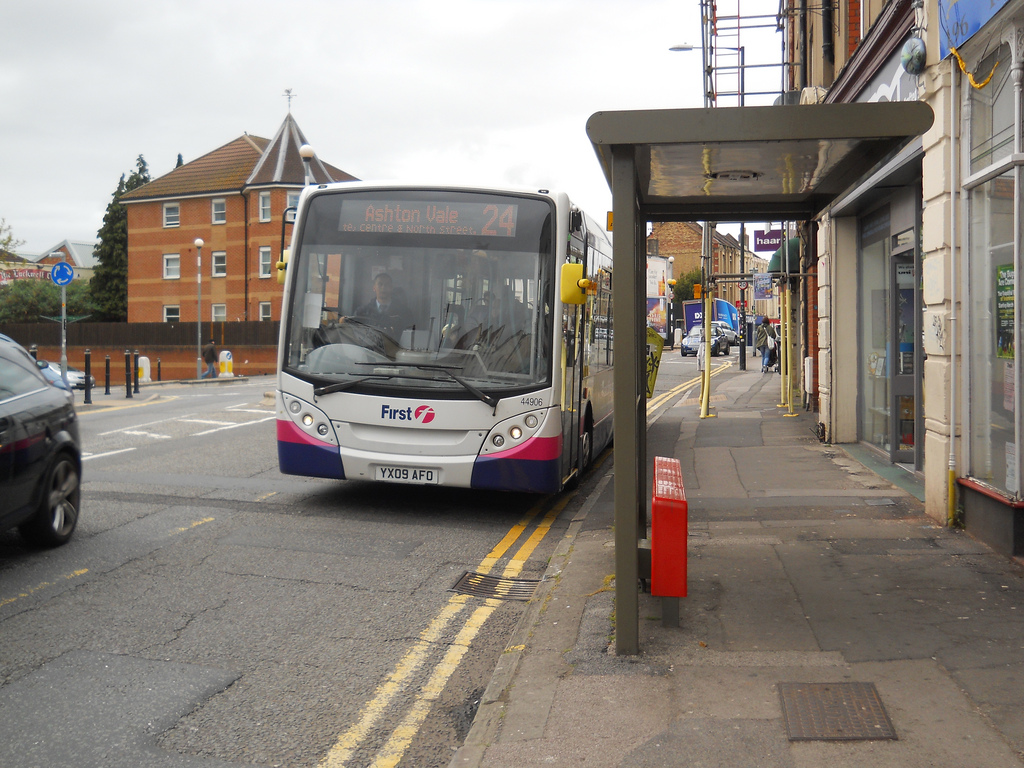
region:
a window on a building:
[152, 198, 173, 224]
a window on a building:
[159, 301, 172, 311]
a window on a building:
[251, 296, 264, 304]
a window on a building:
[163, 238, 170, 268]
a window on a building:
[251, 248, 267, 271]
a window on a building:
[277, 186, 300, 235]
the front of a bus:
[273, 188, 574, 536]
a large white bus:
[229, 148, 670, 488]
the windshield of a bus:
[329, 243, 513, 389]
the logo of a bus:
[337, 401, 456, 431]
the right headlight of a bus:
[254, 393, 337, 451]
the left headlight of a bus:
[457, 412, 556, 464]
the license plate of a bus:
[356, 450, 451, 499]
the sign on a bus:
[335, 186, 528, 251]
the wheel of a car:
[8, 441, 100, 549]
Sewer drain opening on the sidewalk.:
[768, 672, 895, 750]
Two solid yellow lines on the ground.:
[410, 551, 480, 744]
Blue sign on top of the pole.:
[37, 254, 80, 293]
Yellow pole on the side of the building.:
[685, 42, 720, 428]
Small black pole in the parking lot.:
[81, 333, 107, 407]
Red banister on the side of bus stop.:
[645, 432, 693, 603]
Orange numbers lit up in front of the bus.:
[473, 191, 519, 249]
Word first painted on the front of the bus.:
[375, 390, 436, 438]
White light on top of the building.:
[293, 126, 328, 177]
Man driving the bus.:
[357, 262, 405, 327]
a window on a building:
[150, 198, 183, 233]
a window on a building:
[207, 193, 230, 235]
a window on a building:
[242, 192, 271, 230]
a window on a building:
[150, 253, 182, 293]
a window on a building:
[248, 241, 278, 287]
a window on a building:
[154, 294, 178, 327]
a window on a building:
[242, 300, 272, 317]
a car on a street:
[0, 334, 106, 562]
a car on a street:
[670, 303, 734, 373]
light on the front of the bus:
[509, 424, 529, 443]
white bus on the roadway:
[278, 176, 640, 512]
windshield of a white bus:
[293, 231, 554, 394]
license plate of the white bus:
[370, 461, 444, 487]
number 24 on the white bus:
[476, 198, 524, 241]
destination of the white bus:
[360, 199, 462, 225]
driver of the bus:
[335, 266, 413, 339]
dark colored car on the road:
[0, 325, 98, 563]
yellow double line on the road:
[297, 350, 738, 766]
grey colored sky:
[5, 0, 796, 275]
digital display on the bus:
[334, 195, 525, 246]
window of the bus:
[279, 189, 543, 405]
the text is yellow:
[358, 201, 517, 243]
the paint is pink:
[272, 417, 308, 441]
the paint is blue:
[471, 456, 563, 498]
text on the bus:
[377, 398, 420, 421]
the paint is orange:
[118, 191, 240, 322]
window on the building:
[159, 205, 180, 228]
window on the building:
[213, 197, 230, 223]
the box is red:
[652, 451, 692, 594]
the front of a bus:
[269, 177, 617, 498]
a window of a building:
[212, 198, 231, 222]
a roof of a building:
[130, 133, 266, 197]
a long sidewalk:
[469, 319, 1021, 765]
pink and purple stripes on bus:
[485, 421, 556, 494]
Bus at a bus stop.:
[265, 170, 605, 526]